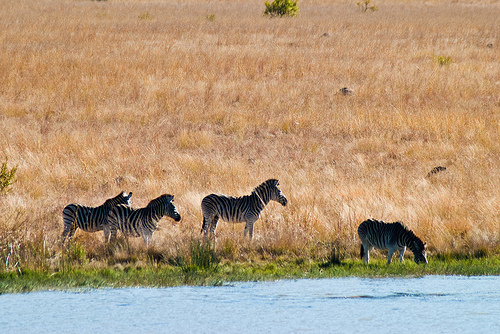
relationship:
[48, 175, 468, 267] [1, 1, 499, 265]
zebras are in a field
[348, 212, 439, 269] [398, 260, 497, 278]
zebra eating grass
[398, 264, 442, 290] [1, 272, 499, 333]
reflection on water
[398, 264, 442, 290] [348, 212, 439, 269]
reflection of zebra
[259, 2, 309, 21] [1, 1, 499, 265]
tree in field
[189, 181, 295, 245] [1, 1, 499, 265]
zebra in field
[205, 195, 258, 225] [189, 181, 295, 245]
stripes are on zebra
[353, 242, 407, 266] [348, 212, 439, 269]
legs are on zebra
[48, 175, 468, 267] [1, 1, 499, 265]
zebras are in field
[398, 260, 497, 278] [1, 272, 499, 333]
grass by water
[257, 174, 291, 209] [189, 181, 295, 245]
head on zebra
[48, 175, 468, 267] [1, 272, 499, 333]
zebras are behind water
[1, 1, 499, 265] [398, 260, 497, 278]
field behind grass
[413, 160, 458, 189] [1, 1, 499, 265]
object in field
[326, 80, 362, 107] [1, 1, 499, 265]
rock in field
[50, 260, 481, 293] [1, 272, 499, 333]
edge of water